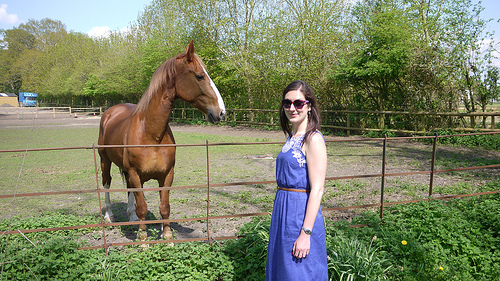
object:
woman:
[264, 80, 329, 281]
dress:
[267, 129, 328, 281]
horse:
[97, 39, 226, 247]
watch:
[301, 226, 312, 234]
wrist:
[298, 225, 314, 236]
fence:
[0, 132, 500, 258]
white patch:
[198, 61, 224, 117]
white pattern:
[290, 135, 306, 171]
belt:
[278, 186, 310, 193]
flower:
[401, 240, 409, 245]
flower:
[437, 266, 446, 271]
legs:
[121, 170, 146, 238]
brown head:
[175, 39, 226, 125]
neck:
[138, 59, 176, 144]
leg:
[99, 155, 112, 213]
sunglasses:
[282, 99, 310, 109]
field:
[0, 118, 500, 281]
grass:
[0, 125, 373, 208]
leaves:
[367, 60, 397, 76]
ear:
[187, 40, 196, 63]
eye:
[194, 73, 203, 81]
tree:
[324, 0, 452, 138]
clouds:
[0, 0, 142, 42]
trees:
[0, 15, 145, 109]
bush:
[324, 231, 394, 281]